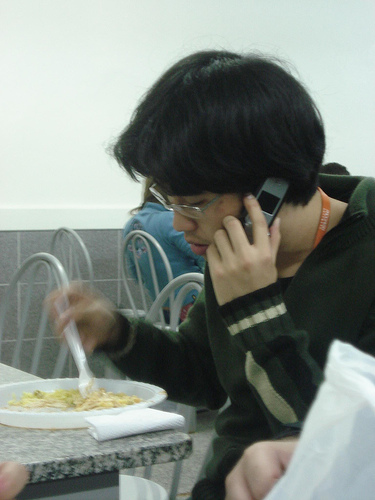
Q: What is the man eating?
A: Noodles.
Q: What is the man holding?
A: Cell phone.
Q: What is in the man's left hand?
A: Cell phone.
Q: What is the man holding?
A: A cell phone.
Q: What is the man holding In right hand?
A: A fork.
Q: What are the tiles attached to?
A: The wall.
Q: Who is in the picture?
A: An asian boy.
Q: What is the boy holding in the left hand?
A: A phone.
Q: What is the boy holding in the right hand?
A: A fork.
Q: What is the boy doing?
A: Eating.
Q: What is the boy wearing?
A: A sweater.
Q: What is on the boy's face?
A: Glasses.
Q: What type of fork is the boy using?
A: A plastic one.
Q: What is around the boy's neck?
A: Orange lariat.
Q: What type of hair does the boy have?
A: Black.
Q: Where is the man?
A: At the table.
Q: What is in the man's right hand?
A: A fork.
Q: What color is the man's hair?
A: Black.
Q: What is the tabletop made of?
A: Marble.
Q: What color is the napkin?
A: White.